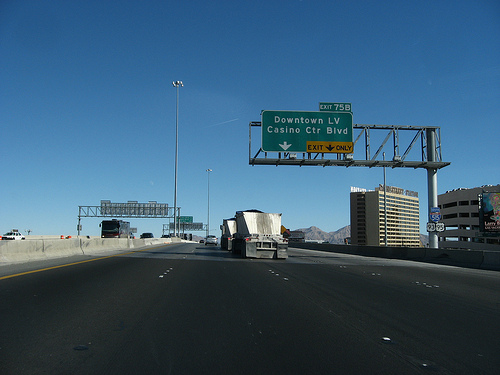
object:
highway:
[1, 239, 496, 374]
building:
[349, 185, 421, 249]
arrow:
[279, 142, 292, 151]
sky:
[1, 0, 495, 254]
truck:
[232, 209, 289, 260]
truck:
[222, 218, 236, 250]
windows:
[470, 199, 479, 206]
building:
[428, 182, 500, 250]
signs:
[427, 222, 445, 232]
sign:
[262, 102, 352, 154]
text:
[267, 126, 300, 133]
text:
[275, 116, 323, 124]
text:
[328, 117, 340, 124]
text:
[326, 127, 348, 135]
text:
[306, 126, 322, 133]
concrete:
[18, 241, 68, 259]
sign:
[429, 207, 442, 222]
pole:
[427, 126, 439, 248]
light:
[170, 81, 185, 238]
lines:
[265, 270, 298, 284]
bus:
[99, 219, 131, 239]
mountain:
[293, 226, 330, 242]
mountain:
[325, 222, 351, 244]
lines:
[159, 267, 173, 278]